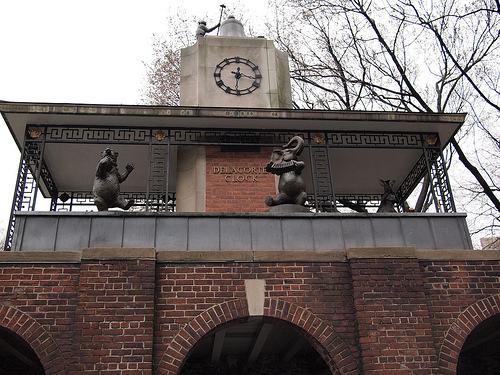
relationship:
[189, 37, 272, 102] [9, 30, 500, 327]
clock on clock tower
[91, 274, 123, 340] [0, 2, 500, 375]
wall of clock tower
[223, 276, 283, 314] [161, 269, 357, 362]
capstone on arch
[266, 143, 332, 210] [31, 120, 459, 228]
statue on 2nd floor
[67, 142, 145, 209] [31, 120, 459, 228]
bear statue on 2nd floor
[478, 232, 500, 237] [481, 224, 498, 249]
roof of odd building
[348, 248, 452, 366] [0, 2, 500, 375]
column of clock tower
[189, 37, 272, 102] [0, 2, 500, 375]
clock on clock tower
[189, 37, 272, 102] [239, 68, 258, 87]
clock has pointed hand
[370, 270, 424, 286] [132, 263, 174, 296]
brick with dark spots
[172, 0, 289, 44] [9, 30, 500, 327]
statue on clock tower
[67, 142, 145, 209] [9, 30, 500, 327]
bear statue on clock tower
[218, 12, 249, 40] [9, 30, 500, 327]
bell on clock tower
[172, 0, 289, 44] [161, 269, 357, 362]
statue over archway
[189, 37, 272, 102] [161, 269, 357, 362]
clock above archway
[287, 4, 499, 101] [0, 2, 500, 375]
tree by clock tower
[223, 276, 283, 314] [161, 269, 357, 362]
capstone on archway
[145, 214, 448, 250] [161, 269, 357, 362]
metal wall over archway